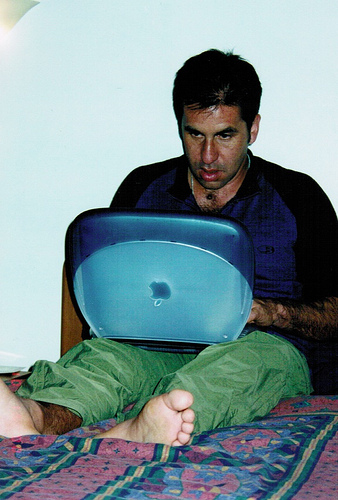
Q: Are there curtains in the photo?
A: No, there are no curtains.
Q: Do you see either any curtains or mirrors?
A: No, there are no curtains or mirrors.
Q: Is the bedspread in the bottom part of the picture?
A: Yes, the bedspread is in the bottom of the image.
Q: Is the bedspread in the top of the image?
A: No, the bedspread is in the bottom of the image.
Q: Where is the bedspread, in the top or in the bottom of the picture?
A: The bedspread is in the bottom of the image.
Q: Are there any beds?
A: Yes, there is a bed.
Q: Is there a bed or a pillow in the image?
A: Yes, there is a bed.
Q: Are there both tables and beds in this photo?
A: No, there is a bed but no tables.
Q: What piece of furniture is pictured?
A: The piece of furniture is a bed.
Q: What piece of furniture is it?
A: The piece of furniture is a bed.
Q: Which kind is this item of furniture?
A: This is a bed.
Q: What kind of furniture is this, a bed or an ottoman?
A: This is a bed.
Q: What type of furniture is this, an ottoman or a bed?
A: This is a bed.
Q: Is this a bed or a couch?
A: This is a bed.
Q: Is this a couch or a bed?
A: This is a bed.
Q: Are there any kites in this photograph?
A: No, there are no kites.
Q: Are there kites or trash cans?
A: No, there are no kites or trash cans.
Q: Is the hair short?
A: Yes, the hair is short.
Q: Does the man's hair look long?
A: No, the hair is short.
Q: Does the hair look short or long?
A: The hair is short.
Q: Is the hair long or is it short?
A: The hair is short.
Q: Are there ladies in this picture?
A: No, there are no ladies.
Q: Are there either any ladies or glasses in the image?
A: No, there are no ladies or glasses.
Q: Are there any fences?
A: No, there are no fences.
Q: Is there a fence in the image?
A: No, there are no fences.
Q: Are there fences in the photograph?
A: No, there are no fences.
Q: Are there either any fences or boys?
A: No, there are no fences or boys.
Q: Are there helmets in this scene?
A: No, there are no helmets.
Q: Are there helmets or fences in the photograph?
A: No, there are no helmets or fences.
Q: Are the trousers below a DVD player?
A: No, the trousers are below the laptop.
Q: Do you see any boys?
A: No, there are no boys.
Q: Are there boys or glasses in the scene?
A: No, there are no boys or glasses.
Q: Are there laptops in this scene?
A: Yes, there is a laptop.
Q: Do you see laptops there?
A: Yes, there is a laptop.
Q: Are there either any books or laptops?
A: Yes, there is a laptop.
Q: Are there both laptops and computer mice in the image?
A: No, there is a laptop but no computer mice.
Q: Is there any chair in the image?
A: No, there are no chairs.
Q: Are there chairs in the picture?
A: No, there are no chairs.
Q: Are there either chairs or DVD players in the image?
A: No, there are no chairs or DVD players.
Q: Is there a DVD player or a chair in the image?
A: No, there are no chairs or DVD players.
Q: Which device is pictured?
A: The device is a laptop.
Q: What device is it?
A: The device is a laptop.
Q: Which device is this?
A: That is a laptop.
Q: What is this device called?
A: That is a laptop.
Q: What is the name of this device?
A: That is a laptop.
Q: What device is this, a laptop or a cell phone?
A: That is a laptop.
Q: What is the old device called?
A: The device is a laptop.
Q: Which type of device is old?
A: The device is a laptop.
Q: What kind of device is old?
A: The device is a laptop.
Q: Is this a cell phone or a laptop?
A: This is a laptop.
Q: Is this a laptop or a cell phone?
A: This is a laptop.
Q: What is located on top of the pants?
A: The laptop computer is on top of the pants.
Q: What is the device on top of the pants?
A: The device is a laptop.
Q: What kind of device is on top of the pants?
A: The device is a laptop.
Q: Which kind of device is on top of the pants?
A: The device is a laptop.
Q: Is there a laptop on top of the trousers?
A: Yes, there is a laptop on top of the trousers.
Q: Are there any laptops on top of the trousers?
A: Yes, there is a laptop on top of the trousers.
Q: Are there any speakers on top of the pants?
A: No, there is a laptop on top of the pants.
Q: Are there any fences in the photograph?
A: No, there are no fences.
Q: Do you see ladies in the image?
A: No, there are no ladies.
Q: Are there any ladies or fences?
A: No, there are no ladies or fences.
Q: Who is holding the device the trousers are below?
A: The man is holding the laptop.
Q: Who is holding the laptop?
A: The man is holding the laptop.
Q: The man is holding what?
A: The man is holding the laptop computer.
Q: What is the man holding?
A: The man is holding the laptop computer.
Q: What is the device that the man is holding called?
A: The device is a laptop.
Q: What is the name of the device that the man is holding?
A: The device is a laptop.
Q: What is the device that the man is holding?
A: The device is a laptop.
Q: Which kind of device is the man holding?
A: The man is holding the laptop.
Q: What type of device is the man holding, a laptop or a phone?
A: The man is holding a laptop.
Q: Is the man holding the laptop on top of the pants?
A: Yes, the man is holding the laptop computer.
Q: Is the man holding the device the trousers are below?
A: Yes, the man is holding the laptop computer.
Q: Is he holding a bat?
A: No, the man is holding the laptop computer.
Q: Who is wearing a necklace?
A: The man is wearing a necklace.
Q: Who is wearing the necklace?
A: The man is wearing a necklace.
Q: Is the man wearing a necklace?
A: Yes, the man is wearing a necklace.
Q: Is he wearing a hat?
A: No, the man is wearing a necklace.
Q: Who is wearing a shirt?
A: The man is wearing a shirt.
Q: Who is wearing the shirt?
A: The man is wearing a shirt.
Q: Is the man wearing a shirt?
A: Yes, the man is wearing a shirt.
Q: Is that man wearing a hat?
A: No, the man is wearing a shirt.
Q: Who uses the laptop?
A: The man uses the laptop.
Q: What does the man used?
A: The man uses a laptop computer.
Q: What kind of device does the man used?
A: The man uses a laptop.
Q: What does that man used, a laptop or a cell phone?
A: The man uses a laptop.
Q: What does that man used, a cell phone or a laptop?
A: The man uses a laptop.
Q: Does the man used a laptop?
A: Yes, the man uses a laptop.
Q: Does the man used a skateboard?
A: No, the man uses a laptop.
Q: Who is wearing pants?
A: The man is wearing pants.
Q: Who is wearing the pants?
A: The man is wearing pants.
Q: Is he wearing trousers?
A: Yes, the man is wearing trousers.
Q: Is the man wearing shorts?
A: No, the man is wearing trousers.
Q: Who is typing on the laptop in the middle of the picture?
A: The man is typing on the laptop computer.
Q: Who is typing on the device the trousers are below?
A: The man is typing on the laptop computer.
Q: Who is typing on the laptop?
A: The man is typing on the laptop computer.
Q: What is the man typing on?
A: The man is typing on the laptop.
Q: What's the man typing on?
A: The man is typing on the laptop.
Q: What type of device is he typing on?
A: The man is typing on the laptop.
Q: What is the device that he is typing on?
A: The device is a laptop.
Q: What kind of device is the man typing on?
A: The man is typing on the laptop.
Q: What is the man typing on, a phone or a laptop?
A: The man is typing on a laptop.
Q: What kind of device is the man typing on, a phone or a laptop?
A: The man is typing on a laptop.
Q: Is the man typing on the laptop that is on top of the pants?
A: Yes, the man is typing on the laptop.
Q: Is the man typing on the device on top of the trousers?
A: Yes, the man is typing on the laptop.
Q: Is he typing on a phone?
A: No, the man is typing on the laptop.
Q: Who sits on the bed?
A: The man sits on the bed.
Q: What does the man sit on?
A: The man sits on the bed.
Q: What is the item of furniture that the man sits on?
A: The piece of furniture is a bed.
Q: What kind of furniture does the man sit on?
A: The man sits on the bed.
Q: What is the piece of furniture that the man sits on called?
A: The piece of furniture is a bed.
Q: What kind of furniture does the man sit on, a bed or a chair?
A: The man sits on a bed.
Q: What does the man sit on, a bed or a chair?
A: The man sits on a bed.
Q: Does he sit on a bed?
A: Yes, the man sits on a bed.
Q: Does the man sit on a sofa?
A: No, the man sits on a bed.